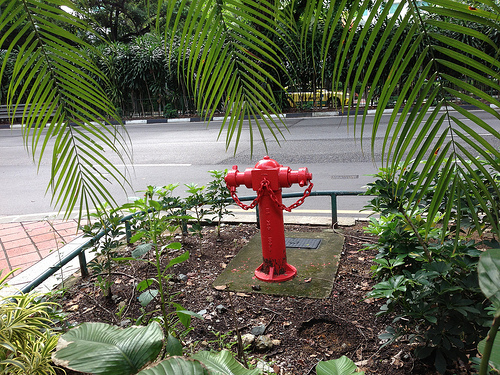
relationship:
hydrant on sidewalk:
[224, 155, 313, 283] [1, 217, 106, 282]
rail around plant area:
[128, 189, 393, 215] [4, 2, 498, 166]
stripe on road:
[81, 155, 194, 170] [0, 106, 495, 276]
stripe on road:
[117, 139, 238, 145] [0, 106, 495, 276]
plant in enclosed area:
[73, 152, 224, 304] [9, 187, 499, 373]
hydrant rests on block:
[224, 155, 313, 284] [213, 225, 345, 301]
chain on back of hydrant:
[221, 181, 303, 211] [171, 154, 333, 279]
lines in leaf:
[73, 323, 162, 368] [52, 321, 164, 373]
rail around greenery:
[1, 189, 392, 308] [101, 207, 191, 284]